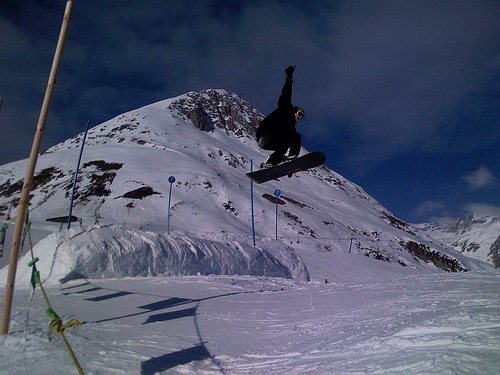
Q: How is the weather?
A: It is cloudy.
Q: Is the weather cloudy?
A: Yes, it is cloudy.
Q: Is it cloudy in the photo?
A: Yes, it is cloudy.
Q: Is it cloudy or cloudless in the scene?
A: It is cloudy.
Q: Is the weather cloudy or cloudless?
A: It is cloudy.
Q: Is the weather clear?
A: No, it is cloudy.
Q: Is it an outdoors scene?
A: Yes, it is outdoors.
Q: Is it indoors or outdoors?
A: It is outdoors.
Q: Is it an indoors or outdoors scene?
A: It is outdoors.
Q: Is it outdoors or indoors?
A: It is outdoors.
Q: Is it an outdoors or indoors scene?
A: It is outdoors.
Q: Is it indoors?
A: No, it is outdoors.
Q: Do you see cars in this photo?
A: No, there are no cars.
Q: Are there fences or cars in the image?
A: No, there are no cars or fences.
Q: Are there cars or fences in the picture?
A: No, there are no cars or fences.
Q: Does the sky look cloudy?
A: Yes, the sky is cloudy.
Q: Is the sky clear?
A: No, the sky is cloudy.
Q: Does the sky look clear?
A: No, the sky is cloudy.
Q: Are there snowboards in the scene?
A: Yes, there is a snowboard.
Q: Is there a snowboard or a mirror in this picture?
A: Yes, there is a snowboard.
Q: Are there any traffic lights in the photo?
A: No, there are no traffic lights.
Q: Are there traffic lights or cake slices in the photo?
A: No, there are no traffic lights or cake slices.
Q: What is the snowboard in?
A: The snowboard is in the air.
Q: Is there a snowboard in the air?
A: Yes, there is a snowboard in the air.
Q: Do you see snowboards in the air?
A: Yes, there is a snowboard in the air.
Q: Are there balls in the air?
A: No, there is a snowboard in the air.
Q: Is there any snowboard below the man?
A: Yes, there is a snowboard below the man.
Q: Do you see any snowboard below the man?
A: Yes, there is a snowboard below the man.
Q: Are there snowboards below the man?
A: Yes, there is a snowboard below the man.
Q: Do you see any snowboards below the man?
A: Yes, there is a snowboard below the man.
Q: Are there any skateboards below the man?
A: No, there is a snowboard below the man.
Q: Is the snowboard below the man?
A: Yes, the snowboard is below the man.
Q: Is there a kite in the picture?
A: No, there are no kites.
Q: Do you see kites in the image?
A: No, there are no kites.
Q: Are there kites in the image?
A: No, there are no kites.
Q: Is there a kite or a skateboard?
A: No, there are no kites or skateboards.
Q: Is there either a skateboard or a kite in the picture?
A: No, there are no kites or skateboards.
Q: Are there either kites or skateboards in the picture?
A: No, there are no kites or skateboards.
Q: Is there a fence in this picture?
A: No, there are no fences.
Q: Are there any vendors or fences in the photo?
A: No, there are no fences or vendors.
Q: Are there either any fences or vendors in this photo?
A: No, there are no fences or vendors.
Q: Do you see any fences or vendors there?
A: No, there are no fences or vendors.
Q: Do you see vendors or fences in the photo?
A: No, there are no fences or vendors.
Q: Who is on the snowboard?
A: The man is on the snowboard.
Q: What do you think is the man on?
A: The man is on the snow board.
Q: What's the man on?
A: The man is on the snow board.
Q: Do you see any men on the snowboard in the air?
A: Yes, there is a man on the snowboard.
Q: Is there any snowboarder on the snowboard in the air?
A: No, there is a man on the snowboard.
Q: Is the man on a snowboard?
A: Yes, the man is on a snowboard.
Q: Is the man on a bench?
A: No, the man is on a snowboard.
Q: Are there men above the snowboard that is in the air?
A: Yes, there is a man above the snowboard.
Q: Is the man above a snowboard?
A: Yes, the man is above a snowboard.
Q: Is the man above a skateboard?
A: No, the man is above a snowboard.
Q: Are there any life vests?
A: No, there are no life vests.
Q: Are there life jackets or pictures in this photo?
A: No, there are no life jackets or pictures.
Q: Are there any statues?
A: No, there are no statues.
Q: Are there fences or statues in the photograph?
A: No, there are no statues or fences.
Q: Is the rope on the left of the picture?
A: Yes, the rope is on the left of the image.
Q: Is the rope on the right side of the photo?
A: No, the rope is on the left of the image.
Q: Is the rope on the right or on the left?
A: The rope is on the left of the image.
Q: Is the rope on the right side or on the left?
A: The rope is on the left of the image.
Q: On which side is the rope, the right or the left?
A: The rope is on the left of the image.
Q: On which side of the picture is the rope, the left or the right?
A: The rope is on the left of the image.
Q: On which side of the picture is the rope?
A: The rope is on the left of the image.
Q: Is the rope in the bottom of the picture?
A: Yes, the rope is in the bottom of the image.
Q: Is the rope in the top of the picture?
A: No, the rope is in the bottom of the image.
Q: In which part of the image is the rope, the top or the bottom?
A: The rope is in the bottom of the image.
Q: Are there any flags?
A: Yes, there is a flag.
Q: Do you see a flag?
A: Yes, there is a flag.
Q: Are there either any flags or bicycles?
A: Yes, there is a flag.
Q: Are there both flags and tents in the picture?
A: No, there is a flag but no tents.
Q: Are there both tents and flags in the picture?
A: No, there is a flag but no tents.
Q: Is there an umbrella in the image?
A: No, there are no umbrellas.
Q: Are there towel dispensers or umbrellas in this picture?
A: No, there are no umbrellas or towel dispensers.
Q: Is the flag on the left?
A: Yes, the flag is on the left of the image.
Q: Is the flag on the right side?
A: No, the flag is on the left of the image.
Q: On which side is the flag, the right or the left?
A: The flag is on the left of the image.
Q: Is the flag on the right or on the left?
A: The flag is on the left of the image.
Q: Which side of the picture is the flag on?
A: The flag is on the left of the image.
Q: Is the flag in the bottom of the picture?
A: Yes, the flag is in the bottom of the image.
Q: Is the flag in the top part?
A: No, the flag is in the bottom of the image.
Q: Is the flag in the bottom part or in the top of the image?
A: The flag is in the bottom of the image.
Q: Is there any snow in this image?
A: Yes, there is snow.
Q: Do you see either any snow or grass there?
A: Yes, there is snow.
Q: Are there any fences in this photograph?
A: No, there are no fences.